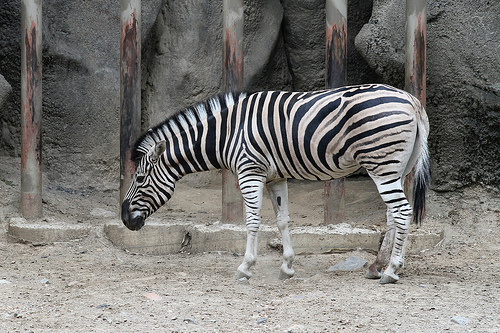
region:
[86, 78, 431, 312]
black and white stripes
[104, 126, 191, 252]
the zebra is looking down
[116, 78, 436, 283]
the zebra in the kennel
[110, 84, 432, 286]
the zebra standing in the dirt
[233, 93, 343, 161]
the horizontal stripes on the body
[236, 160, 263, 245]
the stripes on the leg of the zebra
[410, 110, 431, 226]
the black and white tail of the zebra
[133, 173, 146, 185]
the black eye of the zebra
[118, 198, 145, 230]
the black nose on the face of the zebra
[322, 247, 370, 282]
the stone in the dirt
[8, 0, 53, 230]
the round rail behind the zebra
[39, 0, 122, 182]
the rock wall behind the zebra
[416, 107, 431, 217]
tail on the zebra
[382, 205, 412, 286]
left back foot of zebra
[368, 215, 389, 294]
right back foot of zebra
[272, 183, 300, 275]
right front foot of zebra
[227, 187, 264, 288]
left front foot on zebra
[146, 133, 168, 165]
left ear of zebra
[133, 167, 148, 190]
left eye of zebra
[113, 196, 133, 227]
nose of the zebra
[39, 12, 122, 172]
rocks on other side of poles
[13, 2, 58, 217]
rusted pole in zoo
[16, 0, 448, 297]
this is in a zoo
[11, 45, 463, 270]
this is an animal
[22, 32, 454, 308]
the animal is in captivity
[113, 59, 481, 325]
this is a zebra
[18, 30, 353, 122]
the bars are metal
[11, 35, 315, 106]
the bars are worn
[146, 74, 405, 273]
the zebra is striped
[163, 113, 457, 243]
the zebra is white and black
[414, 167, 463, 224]
the zebras tail is black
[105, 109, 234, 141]
the zebra has a mane